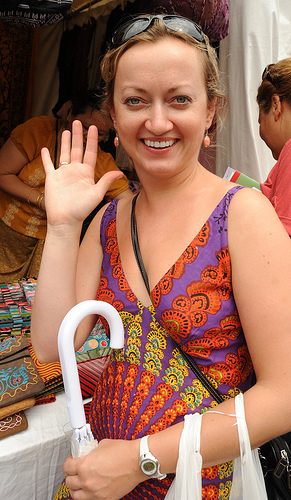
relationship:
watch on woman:
[138, 434, 165, 482] [30, 12, 289, 498]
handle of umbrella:
[56, 299, 125, 428] [57, 298, 125, 457]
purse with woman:
[131, 188, 287, 498] [30, 12, 289, 498]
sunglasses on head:
[109, 13, 210, 53] [103, 13, 220, 179]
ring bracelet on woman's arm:
[24, 186, 45, 206] [0, 114, 47, 206]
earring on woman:
[112, 136, 120, 147] [30, 12, 289, 498]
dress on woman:
[52, 183, 255, 499] [30, 12, 289, 498]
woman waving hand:
[30, 12, 289, 498] [41, 119, 122, 226]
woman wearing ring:
[30, 12, 289, 498] [59, 161, 69, 165]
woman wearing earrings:
[30, 12, 289, 498] [112, 133, 210, 149]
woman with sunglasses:
[30, 12, 289, 498] [109, 13, 210, 53]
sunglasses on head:
[109, 13, 210, 53] [99, 13, 225, 179]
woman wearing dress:
[30, 12, 289, 498] [83, 182, 252, 498]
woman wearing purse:
[30, 12, 289, 498] [131, 188, 287, 498]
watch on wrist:
[136, 434, 165, 482] [128, 430, 167, 487]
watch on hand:
[138, 434, 165, 482] [56, 434, 166, 497]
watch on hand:
[138, 434, 165, 482] [62, 430, 168, 499]